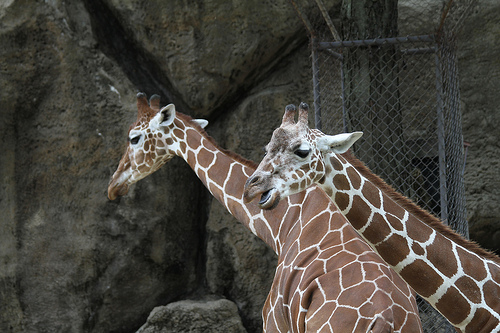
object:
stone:
[144, 295, 239, 330]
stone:
[0, 0, 303, 331]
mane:
[188, 108, 275, 187]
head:
[105, 91, 210, 199]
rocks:
[15, 5, 305, 126]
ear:
[143, 96, 179, 137]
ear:
[180, 108, 215, 129]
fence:
[310, 41, 468, 326]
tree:
[330, 7, 405, 160]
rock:
[9, 16, 324, 331]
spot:
[106, 83, 121, 100]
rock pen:
[0, 0, 497, 331]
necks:
[180, 130, 340, 325]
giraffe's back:
[299, 192, 380, 331]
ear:
[315, 127, 364, 152]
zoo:
[4, 4, 496, 329]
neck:
[243, 106, 495, 294]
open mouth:
[235, 177, 280, 216]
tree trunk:
[338, 9, 429, 247]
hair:
[350, 148, 497, 258]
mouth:
[104, 173, 136, 207]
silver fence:
[291, 0, 472, 237]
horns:
[296, 102, 311, 123]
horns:
[281, 102, 296, 124]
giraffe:
[244, 99, 498, 331]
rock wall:
[4, 19, 321, 306]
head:
[241, 100, 364, 210]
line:
[393, 230, 450, 277]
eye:
[288, 139, 318, 169]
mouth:
[240, 178, 278, 211]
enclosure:
[3, 3, 498, 328]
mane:
[345, 147, 496, 265]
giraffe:
[104, 84, 430, 332]